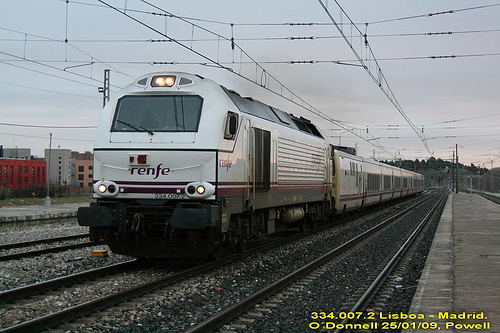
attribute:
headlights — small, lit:
[146, 73, 174, 87]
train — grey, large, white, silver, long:
[72, 62, 433, 267]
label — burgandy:
[126, 158, 171, 180]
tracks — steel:
[20, 260, 170, 322]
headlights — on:
[181, 175, 211, 204]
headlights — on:
[93, 183, 121, 202]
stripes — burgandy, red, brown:
[218, 176, 255, 197]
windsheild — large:
[105, 93, 210, 139]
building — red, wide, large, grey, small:
[40, 146, 77, 191]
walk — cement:
[440, 174, 500, 323]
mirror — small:
[225, 111, 240, 145]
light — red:
[442, 165, 455, 187]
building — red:
[3, 150, 48, 195]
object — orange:
[82, 242, 112, 261]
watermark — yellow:
[305, 302, 496, 330]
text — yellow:
[309, 307, 337, 323]